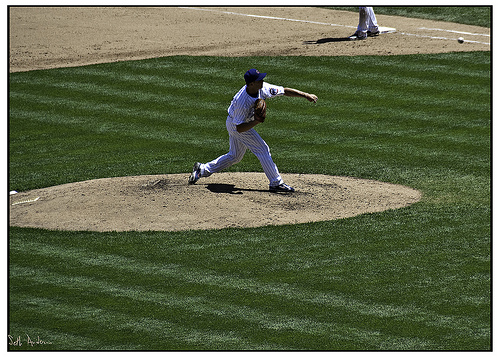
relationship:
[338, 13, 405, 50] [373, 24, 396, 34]
player standing on base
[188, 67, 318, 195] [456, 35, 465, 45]
baseball player throwing baseball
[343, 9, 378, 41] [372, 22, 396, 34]
legs on first base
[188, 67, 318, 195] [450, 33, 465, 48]
baseball player throwing ball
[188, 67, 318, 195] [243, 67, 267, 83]
baseball player wearing cap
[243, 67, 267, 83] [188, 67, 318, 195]
cap on baseball player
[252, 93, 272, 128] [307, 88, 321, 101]
glove on hand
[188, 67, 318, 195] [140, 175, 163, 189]
baseball player extending from rubber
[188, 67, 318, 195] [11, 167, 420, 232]
baseball player on dirt mound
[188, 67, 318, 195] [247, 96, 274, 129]
baseball player with mitt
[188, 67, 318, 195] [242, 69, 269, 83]
baseball player wears cap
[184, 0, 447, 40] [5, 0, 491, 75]
line on dirt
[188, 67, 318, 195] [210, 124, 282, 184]
baseball player has white sock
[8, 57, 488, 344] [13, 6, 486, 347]
grass on infield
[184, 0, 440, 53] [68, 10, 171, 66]
line on dirt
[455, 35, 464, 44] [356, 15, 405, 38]
ball heading to home plate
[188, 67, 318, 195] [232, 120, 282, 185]
baseball player with stripes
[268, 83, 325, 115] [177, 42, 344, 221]
left arm on pitcher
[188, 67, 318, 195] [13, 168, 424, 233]
baseball player standing pitchers mound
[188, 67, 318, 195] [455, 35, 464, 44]
baseball player w a ball